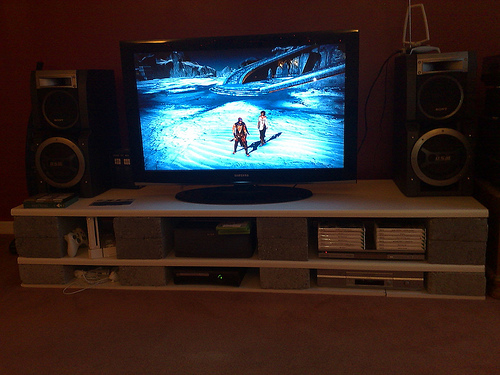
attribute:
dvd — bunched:
[317, 224, 367, 233]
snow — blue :
[147, 109, 224, 164]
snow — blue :
[275, 109, 340, 165]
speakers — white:
[357, 42, 499, 207]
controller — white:
[62, 214, 87, 262]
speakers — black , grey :
[379, 35, 498, 205]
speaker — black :
[15, 51, 130, 196]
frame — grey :
[22, 76, 137, 221]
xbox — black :
[164, 259, 276, 293]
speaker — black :
[369, 43, 489, 220]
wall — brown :
[5, 3, 495, 191]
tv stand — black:
[174, 180, 312, 205]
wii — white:
[79, 210, 102, 258]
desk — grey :
[25, 168, 495, 311]